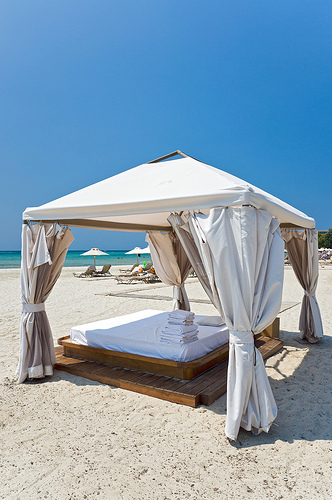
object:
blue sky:
[1, 1, 331, 250]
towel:
[171, 310, 194, 317]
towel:
[168, 324, 198, 335]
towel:
[160, 328, 199, 339]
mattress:
[70, 310, 228, 365]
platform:
[53, 335, 283, 408]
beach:
[0, 262, 328, 498]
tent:
[19, 149, 323, 439]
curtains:
[166, 206, 285, 443]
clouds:
[0, 0, 332, 253]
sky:
[1, 1, 321, 265]